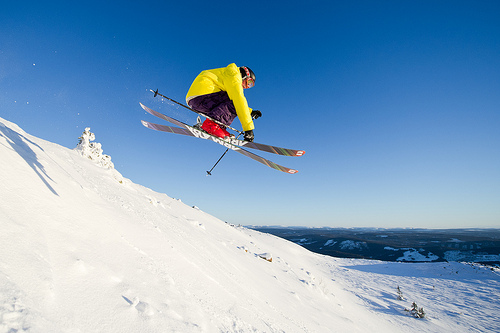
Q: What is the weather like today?
A: It is clear.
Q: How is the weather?
A: It is clear.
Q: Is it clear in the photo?
A: Yes, it is clear.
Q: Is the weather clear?
A: Yes, it is clear.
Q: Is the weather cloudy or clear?
A: It is clear.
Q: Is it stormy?
A: No, it is clear.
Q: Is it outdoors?
A: Yes, it is outdoors.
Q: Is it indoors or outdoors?
A: It is outdoors.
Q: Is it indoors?
A: No, it is outdoors.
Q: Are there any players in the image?
A: No, there are no players.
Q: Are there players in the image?
A: No, there are no players.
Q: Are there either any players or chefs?
A: No, there are no players or chefs.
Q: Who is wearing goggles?
A: The man is wearing goggles.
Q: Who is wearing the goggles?
A: The man is wearing goggles.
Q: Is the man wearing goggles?
A: Yes, the man is wearing goggles.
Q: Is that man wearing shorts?
A: No, the man is wearing goggles.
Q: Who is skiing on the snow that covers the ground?
A: The man is skiing on the snow.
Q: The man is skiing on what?
A: The man is skiing on the snow.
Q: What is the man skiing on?
A: The man is skiing on the snow.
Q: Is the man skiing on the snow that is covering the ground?
A: Yes, the man is skiing on the snow.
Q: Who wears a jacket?
A: The man wears a jacket.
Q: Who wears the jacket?
A: The man wears a jacket.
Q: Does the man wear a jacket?
A: Yes, the man wears a jacket.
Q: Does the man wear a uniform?
A: No, the man wears a jacket.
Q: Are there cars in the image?
A: No, there are no cars.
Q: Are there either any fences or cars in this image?
A: No, there are no cars or fences.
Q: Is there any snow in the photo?
A: Yes, there is snow.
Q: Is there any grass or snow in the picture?
A: Yes, there is snow.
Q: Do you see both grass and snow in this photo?
A: No, there is snow but no grass.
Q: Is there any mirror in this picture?
A: No, there are no mirrors.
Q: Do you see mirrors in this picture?
A: No, there are no mirrors.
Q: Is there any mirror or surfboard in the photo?
A: No, there are no mirrors or surfboards.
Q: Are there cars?
A: No, there are no cars.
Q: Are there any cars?
A: No, there are no cars.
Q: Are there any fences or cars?
A: No, there are no cars or fences.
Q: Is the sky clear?
A: Yes, the sky is clear.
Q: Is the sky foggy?
A: No, the sky is clear.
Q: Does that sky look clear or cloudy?
A: The sky is clear.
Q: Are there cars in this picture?
A: No, there are no cars.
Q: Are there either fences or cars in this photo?
A: No, there are no cars or fences.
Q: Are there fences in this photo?
A: No, there are no fences.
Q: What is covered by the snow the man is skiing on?
A: The ground is covered by the snow.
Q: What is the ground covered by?
A: The ground is covered by the snow.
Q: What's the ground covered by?
A: The ground is covered by the snow.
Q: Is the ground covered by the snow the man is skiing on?
A: Yes, the ground is covered by the snow.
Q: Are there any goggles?
A: Yes, there are goggles.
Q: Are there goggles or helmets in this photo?
A: Yes, there are goggles.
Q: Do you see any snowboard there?
A: No, there are no snowboards.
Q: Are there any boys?
A: No, there are no boys.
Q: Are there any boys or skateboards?
A: No, there are no boys or skateboards.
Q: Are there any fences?
A: No, there are no fences.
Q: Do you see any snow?
A: Yes, there is snow.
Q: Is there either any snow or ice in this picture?
A: Yes, there is snow.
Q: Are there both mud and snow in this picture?
A: No, there is snow but no mud.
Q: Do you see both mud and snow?
A: No, there is snow but no mud.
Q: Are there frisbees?
A: No, there are no frisbees.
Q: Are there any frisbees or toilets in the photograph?
A: No, there are no frisbees or toilets.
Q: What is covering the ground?
A: The snow is covering the ground.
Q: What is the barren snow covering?
A: The snow is covering the ground.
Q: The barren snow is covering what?
A: The snow is covering the ground.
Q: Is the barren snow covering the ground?
A: Yes, the snow is covering the ground.